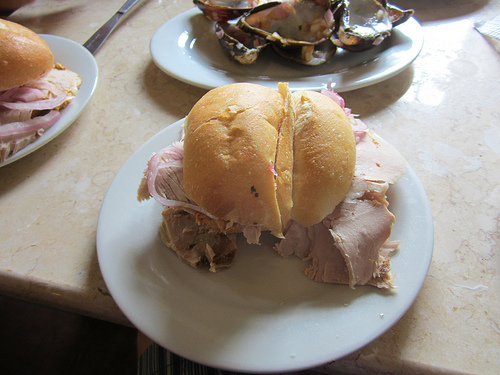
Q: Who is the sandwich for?
A: A person.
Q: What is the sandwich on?
A: A plate.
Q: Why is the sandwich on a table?
A: To be eaten.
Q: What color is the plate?
A: White.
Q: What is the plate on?
A: The counter.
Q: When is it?
A: Day time.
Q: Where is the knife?
A: By a plate.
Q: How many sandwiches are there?
A: Two.